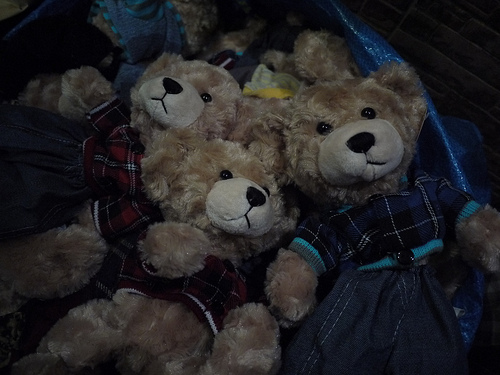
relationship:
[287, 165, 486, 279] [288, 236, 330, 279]
sweater has edge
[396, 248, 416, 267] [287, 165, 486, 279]
button on sweater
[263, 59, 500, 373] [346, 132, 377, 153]
teddy bear has nose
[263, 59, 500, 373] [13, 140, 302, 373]
teddy bear next to teddy bear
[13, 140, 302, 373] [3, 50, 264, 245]
teddy bear next to teddy bear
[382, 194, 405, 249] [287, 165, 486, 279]
line on sweater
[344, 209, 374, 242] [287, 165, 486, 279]
line on sweater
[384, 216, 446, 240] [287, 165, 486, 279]
line on sweater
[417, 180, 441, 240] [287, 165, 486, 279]
line on sweater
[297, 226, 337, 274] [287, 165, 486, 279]
line on sweater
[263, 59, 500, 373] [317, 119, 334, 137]
teddy bear has eye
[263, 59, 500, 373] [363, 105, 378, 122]
teddy bear has eye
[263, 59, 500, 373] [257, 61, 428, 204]
teddy bear has head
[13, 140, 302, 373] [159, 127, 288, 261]
teddy bear has head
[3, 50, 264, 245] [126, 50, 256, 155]
teddy bear has head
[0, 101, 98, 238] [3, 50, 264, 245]
pants are on teddy bear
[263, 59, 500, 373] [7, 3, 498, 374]
teddy bear in bag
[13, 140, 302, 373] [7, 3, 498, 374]
teddy bear in bag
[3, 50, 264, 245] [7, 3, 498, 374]
teddy bear in bag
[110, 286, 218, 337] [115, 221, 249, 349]
stripe on sweater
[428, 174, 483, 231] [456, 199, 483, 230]
sleeve has trim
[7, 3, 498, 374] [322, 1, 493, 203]
bag has edge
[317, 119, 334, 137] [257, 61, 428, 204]
eye in head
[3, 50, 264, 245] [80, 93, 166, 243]
teddy bear wears shirt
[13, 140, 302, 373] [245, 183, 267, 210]
teddy bear has nose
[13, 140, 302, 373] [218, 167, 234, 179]
teddy bear has eye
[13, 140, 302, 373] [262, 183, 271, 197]
teddy bear has eye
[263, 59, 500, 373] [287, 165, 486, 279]
teddy bear wears sweater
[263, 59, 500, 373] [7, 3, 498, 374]
teddy bear in right of bag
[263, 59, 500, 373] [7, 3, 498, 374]
teddy bear lays on bag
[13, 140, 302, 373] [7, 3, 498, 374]
teddy bear lays on bag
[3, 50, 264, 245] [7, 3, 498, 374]
teddy bear lays on bag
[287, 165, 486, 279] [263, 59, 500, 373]
sweater on teddy bear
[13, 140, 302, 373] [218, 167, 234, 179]
teddy bear has right eye